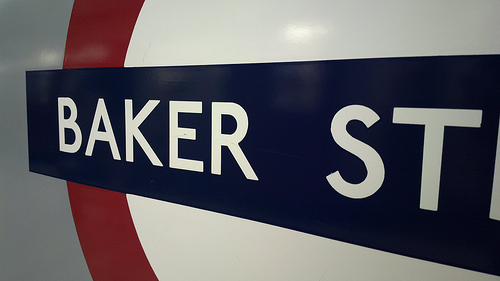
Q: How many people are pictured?
A: None.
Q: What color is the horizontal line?
A: Blue.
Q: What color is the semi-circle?
A: Red.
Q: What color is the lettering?
A: White.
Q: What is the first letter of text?
A: B.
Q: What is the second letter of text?
A: A.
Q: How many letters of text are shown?
A: Seven.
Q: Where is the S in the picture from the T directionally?
A: To the left.